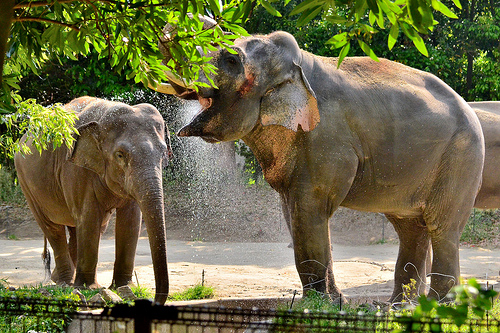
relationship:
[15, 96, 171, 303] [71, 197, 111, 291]
elephant has leg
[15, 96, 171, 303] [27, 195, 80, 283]
elephant has legs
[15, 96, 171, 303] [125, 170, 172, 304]
elephant has trunk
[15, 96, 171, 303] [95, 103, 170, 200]
elephant has face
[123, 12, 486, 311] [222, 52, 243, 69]
elephant has eye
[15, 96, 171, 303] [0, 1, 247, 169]
elephant in trees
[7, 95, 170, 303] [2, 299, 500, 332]
elephant inside fence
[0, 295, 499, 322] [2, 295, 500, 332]
top of fence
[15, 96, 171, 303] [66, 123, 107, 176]
elephant has ear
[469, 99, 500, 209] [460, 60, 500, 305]
elephant not seen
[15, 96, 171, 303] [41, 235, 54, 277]
elephant has tail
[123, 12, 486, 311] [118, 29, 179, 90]
elephant eating leaves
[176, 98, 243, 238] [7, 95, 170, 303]
water behind elephant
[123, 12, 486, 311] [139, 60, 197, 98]
elephant has tusk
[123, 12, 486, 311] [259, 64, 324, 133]
elephant has ear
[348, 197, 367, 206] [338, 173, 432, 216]
part of stomach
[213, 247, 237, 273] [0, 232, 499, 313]
part of floor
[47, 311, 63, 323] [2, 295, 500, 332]
edge of fence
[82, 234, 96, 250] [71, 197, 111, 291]
part of leg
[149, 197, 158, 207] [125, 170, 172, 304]
part of trunk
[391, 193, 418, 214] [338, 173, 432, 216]
edge of stomach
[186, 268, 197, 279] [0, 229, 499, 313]
part of floor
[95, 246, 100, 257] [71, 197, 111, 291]
edge of leg